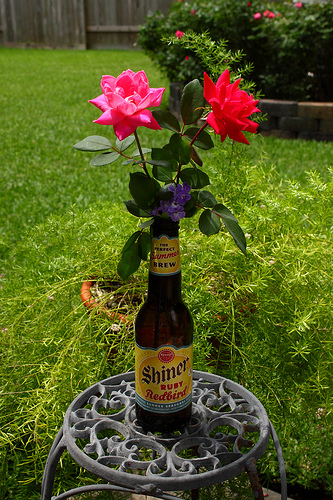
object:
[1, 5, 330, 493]
image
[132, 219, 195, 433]
beer bottle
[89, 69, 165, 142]
flower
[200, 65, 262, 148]
flower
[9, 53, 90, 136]
grass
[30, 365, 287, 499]
stool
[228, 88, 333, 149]
planter pot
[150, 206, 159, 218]
flowers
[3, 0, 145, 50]
fence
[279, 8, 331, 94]
rosebush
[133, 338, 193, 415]
label